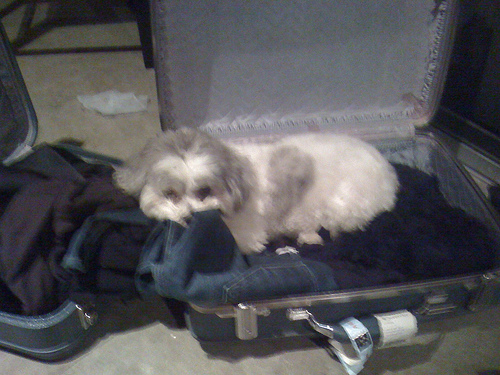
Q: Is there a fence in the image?
A: No, there are no fences.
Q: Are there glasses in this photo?
A: No, there are no glasses.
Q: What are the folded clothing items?
A: The clothing items are jeans.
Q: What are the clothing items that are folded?
A: The clothing items are jeans.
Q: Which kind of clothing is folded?
A: The clothing is jeans.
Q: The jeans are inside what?
A: The jeans are inside the suitcase.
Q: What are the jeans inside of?
A: The jeans are inside the suitcase.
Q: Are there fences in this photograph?
A: No, there are no fences.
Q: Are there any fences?
A: No, there are no fences.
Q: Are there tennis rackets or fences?
A: No, there are no fences or tennis rackets.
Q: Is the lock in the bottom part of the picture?
A: Yes, the lock is in the bottom of the image.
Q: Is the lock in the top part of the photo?
A: No, the lock is in the bottom of the image.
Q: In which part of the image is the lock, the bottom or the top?
A: The lock is in the bottom of the image.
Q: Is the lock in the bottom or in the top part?
A: The lock is in the bottom of the image.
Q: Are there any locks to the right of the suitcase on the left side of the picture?
A: Yes, there is a lock to the right of the suitcase.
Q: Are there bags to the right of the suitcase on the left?
A: No, there is a lock to the right of the suitcase.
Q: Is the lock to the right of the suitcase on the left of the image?
A: Yes, the lock is to the right of the suitcase.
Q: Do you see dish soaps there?
A: No, there are no dish soaps.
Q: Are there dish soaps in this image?
A: No, there are no dish soaps.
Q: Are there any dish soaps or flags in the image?
A: No, there are no dish soaps or flags.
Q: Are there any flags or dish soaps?
A: No, there are no dish soaps or flags.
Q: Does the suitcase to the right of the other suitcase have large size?
A: Yes, the suitcase is large.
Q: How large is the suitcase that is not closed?
A: The suitcase is large.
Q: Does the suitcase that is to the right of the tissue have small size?
A: No, the suitcase is large.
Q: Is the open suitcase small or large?
A: The suitcase is large.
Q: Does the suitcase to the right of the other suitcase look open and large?
A: Yes, the suitcase is open and large.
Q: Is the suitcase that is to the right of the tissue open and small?
A: No, the suitcase is open but large.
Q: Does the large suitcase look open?
A: Yes, the suitcase is open.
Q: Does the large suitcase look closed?
A: No, the suitcase is open.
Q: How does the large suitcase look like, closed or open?
A: The suitcase is open.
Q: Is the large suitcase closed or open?
A: The suitcase is open.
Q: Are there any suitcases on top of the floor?
A: Yes, there is a suitcase on top of the floor.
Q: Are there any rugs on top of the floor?
A: No, there is a suitcase on top of the floor.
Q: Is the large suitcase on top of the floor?
A: Yes, the suitcase is on top of the floor.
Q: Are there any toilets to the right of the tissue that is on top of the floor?
A: No, there is a suitcase to the right of the tissue.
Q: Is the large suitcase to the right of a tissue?
A: Yes, the suitcase is to the right of a tissue.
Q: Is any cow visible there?
A: No, there are no cows.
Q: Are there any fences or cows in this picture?
A: No, there are no cows or fences.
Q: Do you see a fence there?
A: No, there are no fences.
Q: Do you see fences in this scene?
A: No, there are no fences.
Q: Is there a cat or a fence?
A: No, there are no fences or cats.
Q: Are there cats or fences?
A: No, there are no fences or cats.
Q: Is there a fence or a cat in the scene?
A: No, there are no fences or cats.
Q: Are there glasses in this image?
A: No, there are no glasses.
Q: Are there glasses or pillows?
A: No, there are no glasses or pillows.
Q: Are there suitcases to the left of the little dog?
A: Yes, there is a suitcase to the left of the dog.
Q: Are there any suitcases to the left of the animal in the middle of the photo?
A: Yes, there is a suitcase to the left of the dog.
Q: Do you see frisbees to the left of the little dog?
A: No, there is a suitcase to the left of the dog.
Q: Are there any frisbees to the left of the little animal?
A: No, there is a suitcase to the left of the dog.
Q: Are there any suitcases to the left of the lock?
A: Yes, there is a suitcase to the left of the lock.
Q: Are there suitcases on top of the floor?
A: Yes, there is a suitcase on top of the floor.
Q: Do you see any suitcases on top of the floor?
A: Yes, there is a suitcase on top of the floor.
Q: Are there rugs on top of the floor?
A: No, there is a suitcase on top of the floor.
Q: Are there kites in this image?
A: No, there are no kites.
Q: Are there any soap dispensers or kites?
A: No, there are no kites or soap dispensers.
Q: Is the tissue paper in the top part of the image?
A: Yes, the tissue paper is in the top of the image.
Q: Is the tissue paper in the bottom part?
A: No, the tissue paper is in the top of the image.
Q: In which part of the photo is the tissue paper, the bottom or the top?
A: The tissue paper is in the top of the image.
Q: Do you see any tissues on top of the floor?
A: Yes, there is a tissue on top of the floor.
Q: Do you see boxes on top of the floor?
A: No, there is a tissue on top of the floor.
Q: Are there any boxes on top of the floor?
A: No, there is a tissue on top of the floor.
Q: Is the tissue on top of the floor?
A: Yes, the tissue is on top of the floor.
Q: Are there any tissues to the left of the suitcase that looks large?
A: Yes, there is a tissue to the left of the suitcase.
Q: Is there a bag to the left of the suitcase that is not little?
A: No, there is a tissue to the left of the suitcase.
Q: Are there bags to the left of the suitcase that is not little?
A: No, there is a tissue to the left of the suitcase.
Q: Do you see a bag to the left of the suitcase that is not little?
A: No, there is a tissue to the left of the suitcase.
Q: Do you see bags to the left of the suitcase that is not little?
A: No, there is a tissue to the left of the suitcase.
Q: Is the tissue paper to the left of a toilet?
A: No, the tissue paper is to the left of a suitcase.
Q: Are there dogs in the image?
A: Yes, there is a dog.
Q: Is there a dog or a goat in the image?
A: Yes, there is a dog.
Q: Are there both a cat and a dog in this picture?
A: No, there is a dog but no cats.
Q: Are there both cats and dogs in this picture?
A: No, there is a dog but no cats.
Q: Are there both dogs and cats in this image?
A: No, there is a dog but no cats.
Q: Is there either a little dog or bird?
A: Yes, there is a little dog.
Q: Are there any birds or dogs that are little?
A: Yes, the dog is little.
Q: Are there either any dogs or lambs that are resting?
A: Yes, the dog is resting.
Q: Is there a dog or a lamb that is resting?
A: Yes, the dog is resting.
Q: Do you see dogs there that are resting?
A: Yes, there is a dog that is resting.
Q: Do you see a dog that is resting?
A: Yes, there is a dog that is resting.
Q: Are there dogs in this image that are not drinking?
A: Yes, there is a dog that is resting.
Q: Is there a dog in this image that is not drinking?
A: Yes, there is a dog that is resting.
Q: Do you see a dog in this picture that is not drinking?
A: Yes, there is a dog that is resting .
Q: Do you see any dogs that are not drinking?
A: Yes, there is a dog that is resting .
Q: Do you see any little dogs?
A: Yes, there is a little dog.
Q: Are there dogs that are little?
A: Yes, there is a dog that is little.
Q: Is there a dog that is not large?
A: Yes, there is a little dog.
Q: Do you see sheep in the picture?
A: No, there are no sheep.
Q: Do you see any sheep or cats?
A: No, there are no sheep or cats.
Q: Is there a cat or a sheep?
A: No, there are no sheep or cats.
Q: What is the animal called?
A: The animal is a dog.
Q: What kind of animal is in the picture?
A: The animal is a dog.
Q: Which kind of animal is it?
A: The animal is a dog.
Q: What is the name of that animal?
A: This is a dog.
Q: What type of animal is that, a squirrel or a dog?
A: This is a dog.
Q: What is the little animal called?
A: The animal is a dog.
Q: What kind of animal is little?
A: The animal is a dog.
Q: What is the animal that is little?
A: The animal is a dog.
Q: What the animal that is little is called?
A: The animal is a dog.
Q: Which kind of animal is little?
A: The animal is a dog.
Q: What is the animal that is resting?
A: The animal is a dog.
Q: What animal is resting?
A: The animal is a dog.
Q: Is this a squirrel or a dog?
A: This is a dog.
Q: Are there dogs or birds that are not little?
A: No, there is a dog but it is little.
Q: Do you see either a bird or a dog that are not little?
A: No, there is a dog but it is little.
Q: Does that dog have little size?
A: Yes, the dog is little.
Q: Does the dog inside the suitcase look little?
A: Yes, the dog is little.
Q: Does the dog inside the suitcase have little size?
A: Yes, the dog is little.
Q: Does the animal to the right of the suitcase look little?
A: Yes, the dog is little.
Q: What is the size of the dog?
A: The dog is little.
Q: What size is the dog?
A: The dog is little.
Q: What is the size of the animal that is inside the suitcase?
A: The dog is little.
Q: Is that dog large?
A: No, the dog is little.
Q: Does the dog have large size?
A: No, the dog is little.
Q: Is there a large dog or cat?
A: No, there is a dog but it is little.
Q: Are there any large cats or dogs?
A: No, there is a dog but it is little.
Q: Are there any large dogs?
A: No, there is a dog but it is little.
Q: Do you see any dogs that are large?
A: No, there is a dog but it is little.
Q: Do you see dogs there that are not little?
A: No, there is a dog but it is little.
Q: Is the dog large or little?
A: The dog is little.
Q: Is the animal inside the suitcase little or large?
A: The dog is little.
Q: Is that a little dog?
A: Yes, that is a little dog.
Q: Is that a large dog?
A: No, that is a little dog.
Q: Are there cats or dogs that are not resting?
A: No, there is a dog but it is resting.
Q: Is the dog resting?
A: Yes, the dog is resting.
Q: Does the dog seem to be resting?
A: Yes, the dog is resting.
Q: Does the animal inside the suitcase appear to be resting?
A: Yes, the dog is resting.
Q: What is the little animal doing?
A: The dog is resting.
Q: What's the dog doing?
A: The dog is resting.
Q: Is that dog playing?
A: No, the dog is resting.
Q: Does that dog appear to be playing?
A: No, the dog is resting.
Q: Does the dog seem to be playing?
A: No, the dog is resting.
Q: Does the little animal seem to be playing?
A: No, the dog is resting.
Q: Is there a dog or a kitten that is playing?
A: No, there is a dog but it is resting.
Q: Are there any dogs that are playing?
A: No, there is a dog but it is resting.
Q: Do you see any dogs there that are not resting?
A: No, there is a dog but it is resting.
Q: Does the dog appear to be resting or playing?
A: The dog is resting.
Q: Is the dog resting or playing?
A: The dog is resting.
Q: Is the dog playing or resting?
A: The dog is resting.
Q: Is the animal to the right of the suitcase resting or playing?
A: The dog is resting.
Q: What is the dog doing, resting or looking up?
A: The dog is resting.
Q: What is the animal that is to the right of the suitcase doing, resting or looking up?
A: The dog is resting.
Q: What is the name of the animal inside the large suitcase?
A: The animal is a dog.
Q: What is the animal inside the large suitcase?
A: The animal is a dog.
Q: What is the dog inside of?
A: The dog is inside the suitcase.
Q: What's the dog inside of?
A: The dog is inside the suitcase.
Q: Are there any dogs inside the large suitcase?
A: Yes, there is a dog inside the suitcase.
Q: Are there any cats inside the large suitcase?
A: No, there is a dog inside the suitcase.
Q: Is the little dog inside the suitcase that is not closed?
A: Yes, the dog is inside the suitcase.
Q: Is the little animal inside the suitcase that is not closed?
A: Yes, the dog is inside the suitcase.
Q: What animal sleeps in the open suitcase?
A: The dog sleeps in the suitcase.